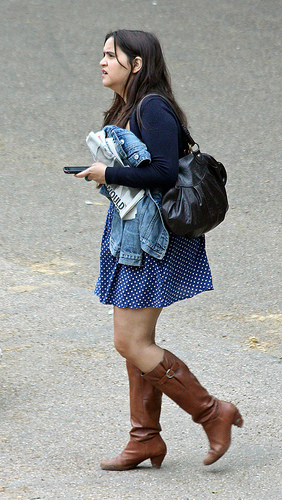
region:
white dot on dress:
[191, 283, 195, 287]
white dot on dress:
[136, 301, 140, 306]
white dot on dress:
[124, 295, 128, 299]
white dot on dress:
[132, 287, 138, 291]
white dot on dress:
[125, 279, 129, 285]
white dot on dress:
[100, 251, 104, 255]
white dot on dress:
[103, 259, 107, 263]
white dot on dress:
[180, 244, 183, 247]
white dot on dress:
[202, 257, 208, 261]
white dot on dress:
[146, 257, 151, 261]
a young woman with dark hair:
[60, 27, 244, 470]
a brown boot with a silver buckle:
[142, 349, 244, 467]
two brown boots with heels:
[98, 350, 243, 470]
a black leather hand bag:
[134, 93, 228, 236]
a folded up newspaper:
[85, 130, 145, 221]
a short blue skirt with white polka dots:
[93, 193, 212, 307]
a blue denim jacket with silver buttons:
[97, 124, 168, 265]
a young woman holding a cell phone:
[62, 29, 243, 470]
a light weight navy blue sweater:
[104, 92, 188, 189]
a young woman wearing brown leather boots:
[61, 27, 243, 470]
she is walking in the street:
[49, 24, 254, 475]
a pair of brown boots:
[86, 341, 258, 481]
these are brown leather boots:
[88, 339, 255, 489]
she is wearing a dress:
[62, 15, 243, 301]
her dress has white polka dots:
[102, 201, 225, 317]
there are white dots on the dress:
[95, 243, 221, 311]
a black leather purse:
[124, 90, 249, 243]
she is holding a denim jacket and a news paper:
[74, 115, 192, 268]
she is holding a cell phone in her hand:
[56, 159, 130, 189]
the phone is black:
[53, 155, 91, 174]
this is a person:
[74, 27, 247, 468]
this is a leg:
[112, 288, 252, 468]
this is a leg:
[91, 366, 175, 482]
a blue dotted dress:
[92, 196, 219, 317]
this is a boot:
[145, 349, 246, 477]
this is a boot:
[93, 358, 166, 476]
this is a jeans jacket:
[80, 123, 174, 272]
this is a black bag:
[153, 152, 233, 239]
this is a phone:
[60, 159, 99, 188]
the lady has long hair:
[90, 25, 196, 151]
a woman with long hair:
[103, 26, 172, 123]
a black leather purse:
[157, 119, 234, 233]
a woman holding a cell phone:
[57, 159, 100, 184]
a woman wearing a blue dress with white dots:
[152, 247, 198, 297]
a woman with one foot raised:
[179, 390, 247, 479]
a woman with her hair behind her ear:
[133, 43, 147, 88]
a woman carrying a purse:
[135, 95, 208, 222]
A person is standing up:
[71, 24, 243, 459]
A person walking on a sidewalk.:
[94, 250, 234, 487]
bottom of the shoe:
[91, 428, 173, 487]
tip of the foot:
[91, 445, 126, 477]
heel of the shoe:
[146, 440, 179, 483]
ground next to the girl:
[13, 439, 84, 494]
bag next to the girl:
[149, 140, 234, 219]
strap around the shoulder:
[135, 83, 187, 125]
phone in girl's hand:
[52, 153, 103, 190]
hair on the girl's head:
[116, 28, 176, 57]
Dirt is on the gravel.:
[241, 330, 261, 354]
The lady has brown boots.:
[120, 353, 229, 469]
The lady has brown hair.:
[104, 23, 185, 110]